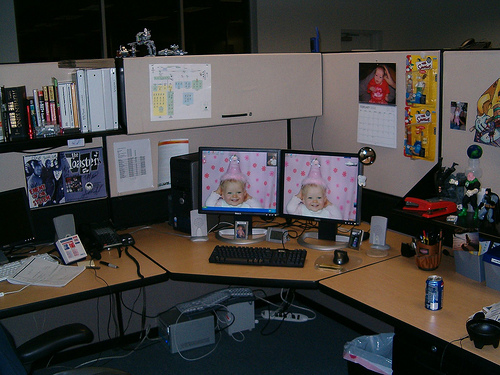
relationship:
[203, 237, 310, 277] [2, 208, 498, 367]
black keyboard on desk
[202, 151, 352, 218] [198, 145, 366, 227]
pictures on monitors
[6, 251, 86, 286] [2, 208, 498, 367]
notebook on desk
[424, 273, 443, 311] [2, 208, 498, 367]
can on desk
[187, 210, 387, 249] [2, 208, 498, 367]
speakers on desk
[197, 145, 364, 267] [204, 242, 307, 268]
computer has keyboard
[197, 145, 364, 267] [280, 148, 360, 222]
computer has screen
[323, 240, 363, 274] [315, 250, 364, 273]
computer mouse on pad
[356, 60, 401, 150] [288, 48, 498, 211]
calendar on wall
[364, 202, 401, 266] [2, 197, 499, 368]
computer speaker on table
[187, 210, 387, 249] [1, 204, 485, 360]
speakers on table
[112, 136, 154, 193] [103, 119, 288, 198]
list on board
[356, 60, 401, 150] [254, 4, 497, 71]
calendar on wall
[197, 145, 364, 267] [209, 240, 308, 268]
computer has keyboard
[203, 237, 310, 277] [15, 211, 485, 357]
black keyboard on desk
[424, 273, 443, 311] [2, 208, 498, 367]
can on a desk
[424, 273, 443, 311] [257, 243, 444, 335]
can on a desk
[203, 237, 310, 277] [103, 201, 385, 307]
black keyboard on a desk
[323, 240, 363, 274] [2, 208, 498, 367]
computer mouse on a desk